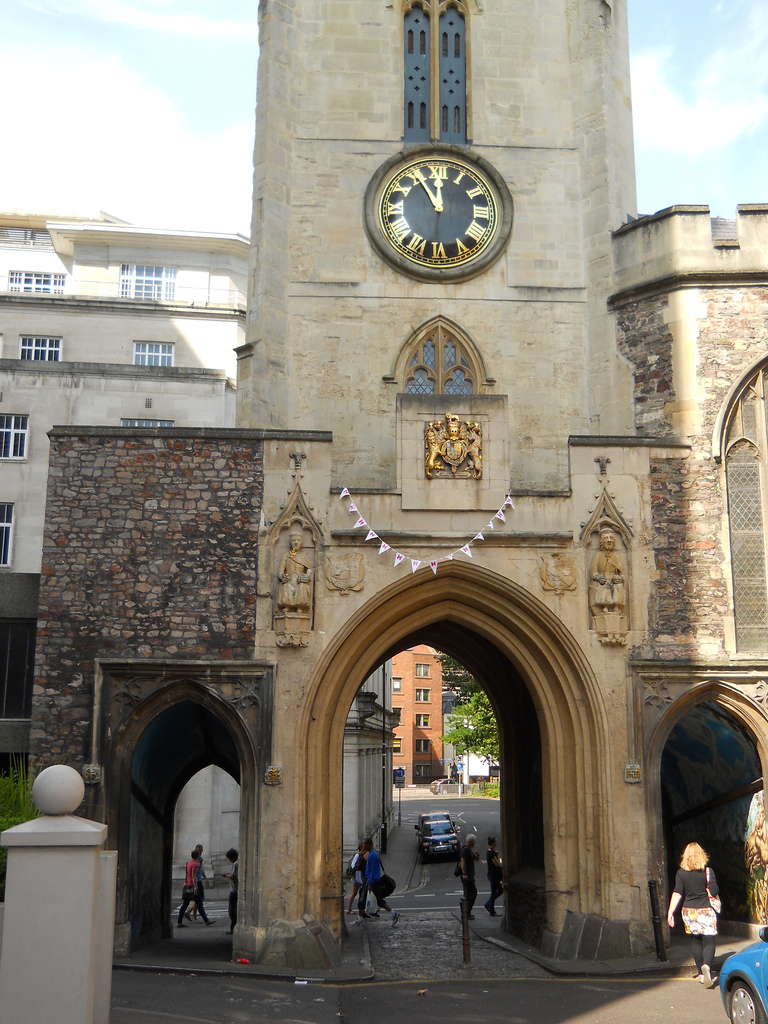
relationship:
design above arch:
[420, 411, 487, 482] [294, 558, 612, 977]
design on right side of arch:
[579, 453, 640, 648] [294, 558, 612, 950]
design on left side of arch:
[266, 446, 327, 647] [294, 558, 612, 950]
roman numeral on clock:
[427, 157, 450, 180] [363, 136, 525, 295]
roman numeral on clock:
[449, 164, 471, 186] [363, 136, 525, 295]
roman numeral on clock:
[463, 182, 488, 200] [363, 136, 525, 295]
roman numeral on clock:
[468, 203, 491, 221] [363, 136, 525, 295]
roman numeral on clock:
[466, 217, 489, 244] [363, 136, 525, 295]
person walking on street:
[354, 834, 398, 927] [348, 797, 553, 988]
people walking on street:
[458, 833, 478, 921] [348, 797, 553, 988]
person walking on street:
[482, 831, 507, 918] [348, 797, 553, 988]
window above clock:
[391, 5, 475, 134] [365, 142, 515, 284]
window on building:
[391, 5, 475, 134] [30, 6, 767, 980]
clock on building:
[365, 142, 515, 284] [30, 6, 767, 980]